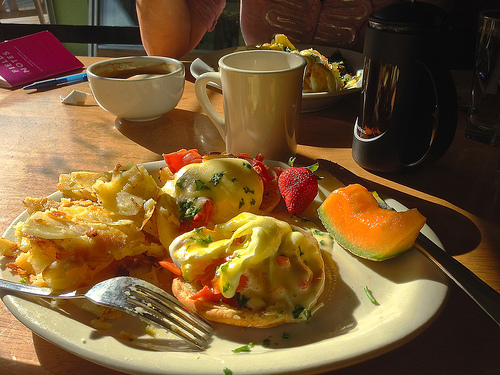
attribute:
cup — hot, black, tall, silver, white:
[356, 8, 462, 177]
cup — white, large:
[196, 43, 313, 167]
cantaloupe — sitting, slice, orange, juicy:
[321, 175, 427, 267]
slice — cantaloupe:
[314, 182, 434, 272]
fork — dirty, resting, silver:
[3, 273, 219, 348]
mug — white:
[192, 45, 309, 163]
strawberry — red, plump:
[277, 156, 324, 219]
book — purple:
[0, 29, 85, 89]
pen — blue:
[24, 73, 92, 96]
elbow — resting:
[136, 1, 210, 61]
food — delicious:
[5, 146, 428, 333]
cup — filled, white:
[81, 51, 190, 131]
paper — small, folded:
[55, 88, 101, 107]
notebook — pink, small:
[0, 23, 84, 86]